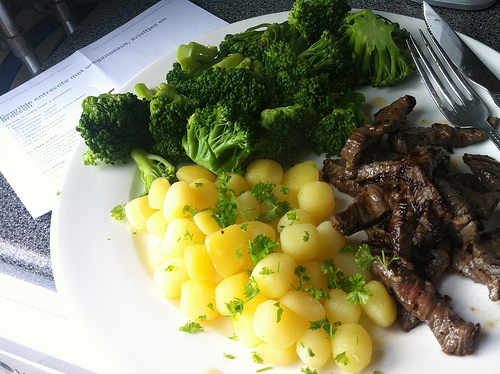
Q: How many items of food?
A: Three.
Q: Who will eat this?
A: Woman.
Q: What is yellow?
A: Corn.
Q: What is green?
A: Broccoli.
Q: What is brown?
A: Meat.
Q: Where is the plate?
A: On the table.